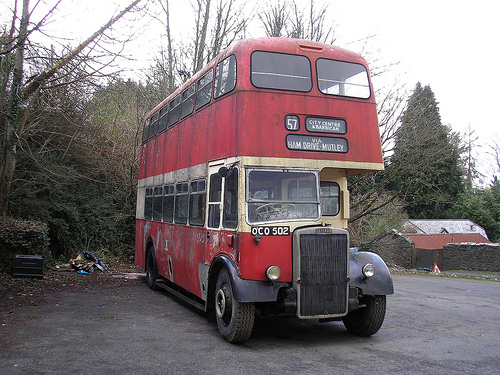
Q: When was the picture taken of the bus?
A: Daytime.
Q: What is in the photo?
A: A bus.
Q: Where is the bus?
A: A parking lot.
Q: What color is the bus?
A: Red.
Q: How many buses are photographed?
A: One.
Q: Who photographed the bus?
A: The bus owner.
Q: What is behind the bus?
A: Trees.